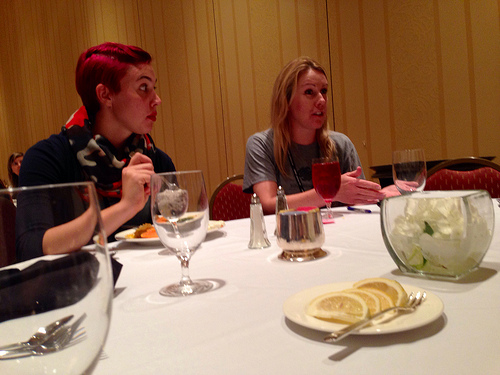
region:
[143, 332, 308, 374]
the table clothe is white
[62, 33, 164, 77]
her hair is red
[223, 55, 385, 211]
she is blonde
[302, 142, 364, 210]
the glass has orange juice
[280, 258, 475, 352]
lemon slices are on the plate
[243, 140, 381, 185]
her shirt is grey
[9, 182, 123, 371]
the glass is empty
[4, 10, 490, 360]
they are indoors in a restaraunt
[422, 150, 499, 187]
the chairs are red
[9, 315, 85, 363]
the forks are silver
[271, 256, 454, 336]
a small plate on the table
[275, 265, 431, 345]
lemons are on the plate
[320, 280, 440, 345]
the fork is silver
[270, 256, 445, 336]
the plate is round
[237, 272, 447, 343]
the plate is white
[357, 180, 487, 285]
a glass bowl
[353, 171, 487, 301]
a bowl of flowers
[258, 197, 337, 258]
a container with sugar packs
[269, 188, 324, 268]
a silver metal container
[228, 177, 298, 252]
salt and pepper shakers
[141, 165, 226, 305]
An empty glass on the table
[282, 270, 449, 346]
A plate of lemon slices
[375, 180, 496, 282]
A glass center piece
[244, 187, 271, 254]
A slim salt shaker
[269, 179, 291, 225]
Part of a pepper shaker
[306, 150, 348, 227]
A glass filled with red liquid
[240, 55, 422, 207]
A blonde woman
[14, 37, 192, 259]
A woman with red hair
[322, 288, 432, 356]
A small fork on a plate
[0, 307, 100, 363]
Silverware on the table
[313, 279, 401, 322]
the sliced lemons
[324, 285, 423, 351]
the small silver fork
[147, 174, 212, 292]
the glass filled with water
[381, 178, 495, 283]
the flower in the vase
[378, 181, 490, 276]
the small glass vase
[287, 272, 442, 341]
the small white plate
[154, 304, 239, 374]
the white table cloth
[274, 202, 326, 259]
the small silver cup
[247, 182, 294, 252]
the salt and pepper shakers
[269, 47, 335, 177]
the long blond hair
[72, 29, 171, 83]
girl has red hair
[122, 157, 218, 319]
clear glass filled with water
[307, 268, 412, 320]
lemon slices on white dish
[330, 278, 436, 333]
silver fork on plate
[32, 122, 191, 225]
girl has black hoodie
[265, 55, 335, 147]
girl has brown hair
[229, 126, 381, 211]
girl has grey shirt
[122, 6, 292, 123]
light brown wall behind women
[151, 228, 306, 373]
food on white table cloth